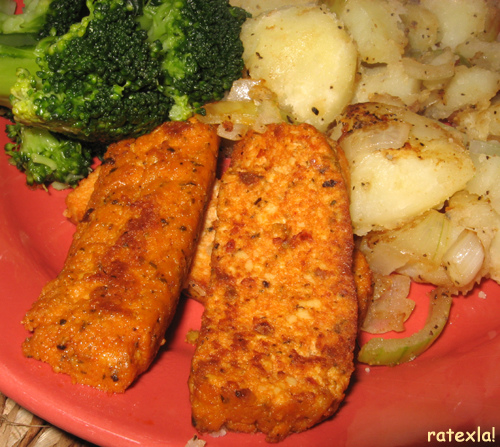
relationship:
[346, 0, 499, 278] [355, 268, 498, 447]
potatoes on plate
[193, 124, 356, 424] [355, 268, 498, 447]
fish on plate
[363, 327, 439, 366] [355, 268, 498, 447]
onion on plate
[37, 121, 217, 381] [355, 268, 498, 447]
fish on plate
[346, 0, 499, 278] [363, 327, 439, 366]
potatoes next to onion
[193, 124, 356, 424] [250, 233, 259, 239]
fish has seasoning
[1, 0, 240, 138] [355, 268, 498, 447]
brocolli on plate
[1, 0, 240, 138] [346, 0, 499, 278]
brocolli next to potatoes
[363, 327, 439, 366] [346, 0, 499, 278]
onion next to potatoes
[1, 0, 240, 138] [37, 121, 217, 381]
brocolli next to fish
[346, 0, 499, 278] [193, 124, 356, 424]
potatoes next to fish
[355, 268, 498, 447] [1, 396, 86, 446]
plate on table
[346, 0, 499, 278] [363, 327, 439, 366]
potatoes fried with onion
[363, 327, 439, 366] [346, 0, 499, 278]
onion below potatoes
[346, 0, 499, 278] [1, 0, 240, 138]
potatoes next to brocolli